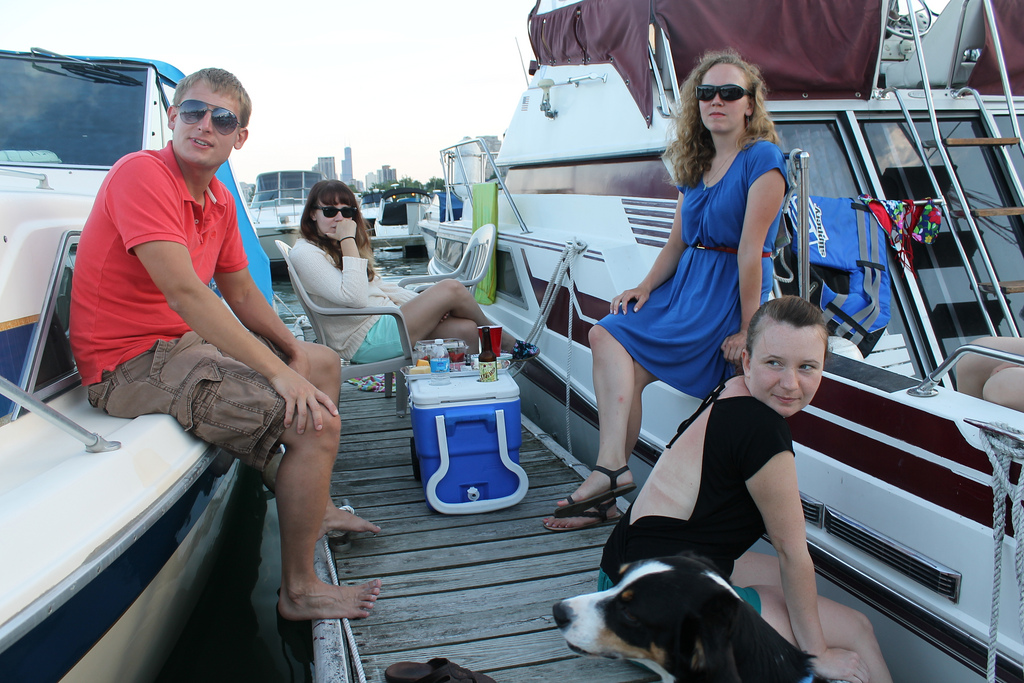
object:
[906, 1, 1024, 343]
ladder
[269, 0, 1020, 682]
boat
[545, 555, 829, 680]
dog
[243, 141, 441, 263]
boats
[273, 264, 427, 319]
water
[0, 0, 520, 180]
sky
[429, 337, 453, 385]
bottle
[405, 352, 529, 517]
box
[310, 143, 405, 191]
buildings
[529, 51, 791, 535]
woman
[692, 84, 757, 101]
eye glass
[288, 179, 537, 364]
woman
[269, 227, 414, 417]
chair